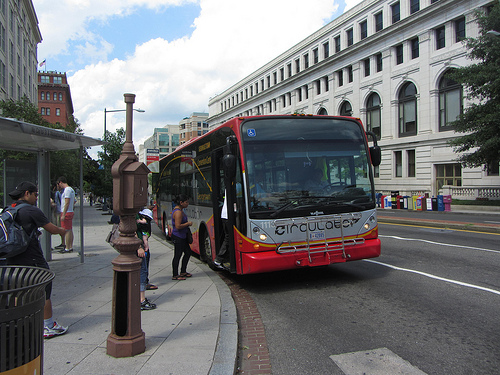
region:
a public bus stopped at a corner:
[111, 94, 393, 324]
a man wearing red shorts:
[58, 171, 75, 236]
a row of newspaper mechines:
[379, 187, 459, 213]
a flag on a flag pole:
[28, 47, 58, 79]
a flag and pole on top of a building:
[36, 55, 54, 91]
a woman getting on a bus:
[158, 127, 239, 292]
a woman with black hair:
[176, 189, 195, 213]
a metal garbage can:
[1, 259, 51, 374]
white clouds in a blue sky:
[106, 7, 235, 68]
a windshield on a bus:
[223, 112, 385, 241]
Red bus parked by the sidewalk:
[97, 101, 399, 329]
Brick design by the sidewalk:
[237, 315, 267, 365]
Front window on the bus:
[241, 111, 388, 230]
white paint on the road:
[382, 255, 486, 317]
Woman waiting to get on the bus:
[160, 190, 202, 309]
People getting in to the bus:
[210, 151, 242, 273]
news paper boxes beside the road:
[386, 176, 495, 240]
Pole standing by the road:
[100, 60, 148, 370]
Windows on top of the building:
[257, 68, 403, 94]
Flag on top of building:
[35, 50, 68, 85]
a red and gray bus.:
[145, 102, 385, 277]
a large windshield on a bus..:
[243, 118, 378, 224]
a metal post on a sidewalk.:
[97, 89, 162, 362]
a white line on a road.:
[357, 251, 496, 318]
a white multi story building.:
[204, 1, 497, 208]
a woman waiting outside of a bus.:
[163, 185, 210, 285]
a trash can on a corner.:
[0, 254, 84, 373]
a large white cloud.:
[68, 0, 345, 155]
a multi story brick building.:
[39, 65, 93, 137]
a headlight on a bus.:
[253, 230, 265, 246]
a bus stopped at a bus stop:
[18, 39, 438, 359]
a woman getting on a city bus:
[152, 142, 267, 277]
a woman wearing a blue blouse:
[163, 188, 203, 283]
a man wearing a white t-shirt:
[46, 175, 81, 257]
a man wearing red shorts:
[48, 172, 83, 254]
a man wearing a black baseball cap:
[0, 178, 73, 337]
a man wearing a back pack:
[1, 177, 73, 334]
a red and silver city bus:
[131, 100, 396, 285]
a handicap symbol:
[243, 123, 258, 140]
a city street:
[236, 266, 498, 364]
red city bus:
[154, 117, 377, 276]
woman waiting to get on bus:
[165, 191, 195, 288]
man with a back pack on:
[1, 178, 63, 347]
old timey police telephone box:
[104, 88, 151, 358]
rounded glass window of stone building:
[392, 70, 422, 141]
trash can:
[7, 265, 57, 372]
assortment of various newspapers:
[377, 190, 453, 209]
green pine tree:
[447, 5, 499, 182]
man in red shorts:
[54, 175, 74, 262]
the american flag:
[38, 55, 50, 70]